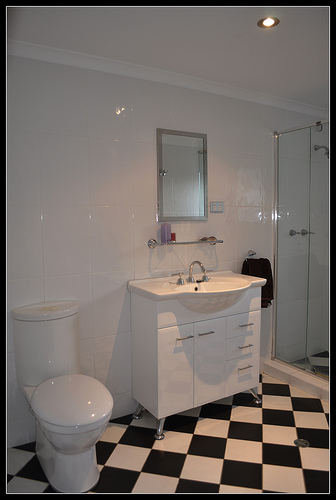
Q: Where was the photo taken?
A: Bathroom.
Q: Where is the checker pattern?
A: Floor.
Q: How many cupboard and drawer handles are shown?
A: 5.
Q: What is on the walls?
A: Tiles.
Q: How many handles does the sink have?
A: 2.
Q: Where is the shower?
A: On the right.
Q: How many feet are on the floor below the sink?
A: 3.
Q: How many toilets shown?
A: 1.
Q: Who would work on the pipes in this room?
A: Plumber.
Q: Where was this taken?
A: Bathroom.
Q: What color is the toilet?
A: White.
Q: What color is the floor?
A: Black and white.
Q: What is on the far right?
A: Shower door.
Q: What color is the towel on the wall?
A: Black.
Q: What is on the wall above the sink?
A: Mirror.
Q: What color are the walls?
A: White.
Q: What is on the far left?
A: Toilet.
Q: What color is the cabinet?
A: White.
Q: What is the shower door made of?
A: Glass.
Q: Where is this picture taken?
A: Bathroom.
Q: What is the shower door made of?
A: Glass.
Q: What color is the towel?
A: Black.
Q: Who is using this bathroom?
A: Owners of the house.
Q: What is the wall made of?
A: Tile.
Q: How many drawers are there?
A: Three.